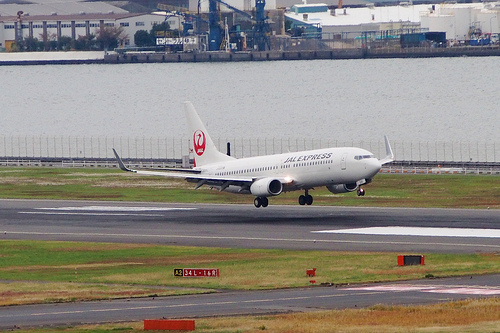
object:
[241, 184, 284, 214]
part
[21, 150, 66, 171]
part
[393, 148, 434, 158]
part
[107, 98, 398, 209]
jet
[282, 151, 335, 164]
lettering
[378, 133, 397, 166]
left wing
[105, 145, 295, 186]
right wing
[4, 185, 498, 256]
runway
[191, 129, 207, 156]
symbol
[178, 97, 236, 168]
tail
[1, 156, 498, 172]
wall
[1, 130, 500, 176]
fence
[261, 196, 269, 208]
right wheels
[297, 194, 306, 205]
left wheels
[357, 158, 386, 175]
nose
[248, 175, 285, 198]
engine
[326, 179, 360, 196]
engine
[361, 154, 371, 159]
windshield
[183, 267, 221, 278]
sign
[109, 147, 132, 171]
tip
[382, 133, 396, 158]
tip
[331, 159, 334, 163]
passenger windows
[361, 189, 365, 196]
front wheel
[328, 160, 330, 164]
window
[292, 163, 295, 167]
window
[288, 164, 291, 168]
window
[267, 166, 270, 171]
window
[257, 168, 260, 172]
window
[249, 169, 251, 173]
window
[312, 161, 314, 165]
window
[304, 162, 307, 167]
window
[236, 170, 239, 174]
window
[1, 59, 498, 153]
water